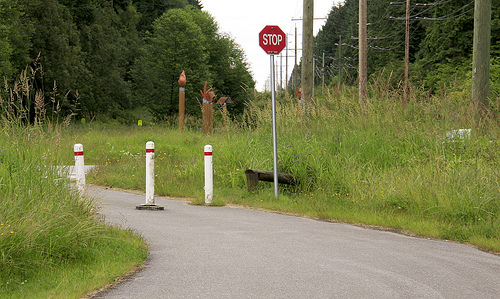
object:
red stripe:
[203, 151, 212, 156]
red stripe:
[145, 148, 154, 153]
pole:
[301, 0, 312, 110]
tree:
[125, 8, 231, 127]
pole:
[73, 142, 86, 203]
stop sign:
[258, 24, 287, 56]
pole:
[144, 140, 155, 204]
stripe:
[74, 147, 82, 156]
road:
[49, 164, 499, 297]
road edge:
[79, 215, 151, 297]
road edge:
[84, 176, 499, 256]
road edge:
[49, 162, 102, 165]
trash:
[445, 125, 478, 143]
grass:
[0, 62, 500, 296]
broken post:
[238, 167, 301, 194]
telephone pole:
[403, 0, 410, 103]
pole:
[293, 26, 297, 92]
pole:
[357, 0, 367, 113]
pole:
[321, 49, 327, 95]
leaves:
[113, 54, 139, 69]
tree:
[25, 0, 101, 124]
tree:
[205, 31, 260, 131]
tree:
[411, 0, 500, 100]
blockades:
[133, 139, 165, 211]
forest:
[0, 0, 500, 125]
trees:
[0, 0, 44, 124]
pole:
[202, 144, 214, 203]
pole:
[466, 0, 495, 142]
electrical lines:
[250, 0, 465, 70]